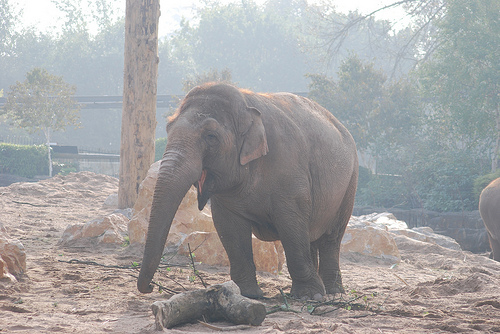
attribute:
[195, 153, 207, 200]
mouth — open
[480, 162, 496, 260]
elephant — partially-seen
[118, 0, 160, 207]
pole — wood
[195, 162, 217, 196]
tongue — pink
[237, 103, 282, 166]
ears — small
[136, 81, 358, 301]
elephant — smiling, young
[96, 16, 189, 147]
tree bark — brown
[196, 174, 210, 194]
tongue — pink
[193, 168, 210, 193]
tongue —  Pink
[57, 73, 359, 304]
elephant — young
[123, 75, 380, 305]
elephant — gray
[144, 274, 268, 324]
log — v-shaped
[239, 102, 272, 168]
ear — small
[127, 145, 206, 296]
tongue — pink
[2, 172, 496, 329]
ground — dirt, rough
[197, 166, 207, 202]
tongue — pink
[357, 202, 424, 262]
rocks — large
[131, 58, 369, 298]
elephant — happy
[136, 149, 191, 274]
trunk — long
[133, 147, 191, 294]
trunk —  of elephant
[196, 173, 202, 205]
tongue —  Pink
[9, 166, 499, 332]
area — enclosed